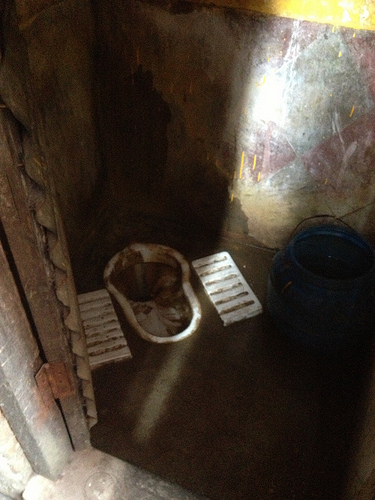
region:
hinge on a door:
[24, 357, 79, 411]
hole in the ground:
[97, 231, 216, 347]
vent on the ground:
[185, 250, 263, 335]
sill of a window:
[49, 439, 172, 498]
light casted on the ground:
[147, 343, 180, 456]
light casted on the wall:
[273, 29, 346, 200]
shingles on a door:
[57, 276, 113, 437]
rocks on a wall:
[1, 407, 56, 498]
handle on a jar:
[288, 213, 358, 234]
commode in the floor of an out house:
[103, 242, 200, 341]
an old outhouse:
[1, 2, 372, 497]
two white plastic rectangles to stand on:
[77, 251, 263, 367]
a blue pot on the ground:
[265, 215, 371, 355]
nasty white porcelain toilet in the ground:
[106, 236, 202, 341]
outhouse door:
[3, 47, 95, 445]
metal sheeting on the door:
[3, 14, 96, 429]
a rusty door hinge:
[35, 361, 73, 407]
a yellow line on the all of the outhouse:
[216, 0, 370, 26]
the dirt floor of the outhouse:
[86, 212, 358, 495]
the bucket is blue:
[264, 212, 371, 359]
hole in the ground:
[102, 239, 204, 346]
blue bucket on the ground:
[262, 210, 367, 355]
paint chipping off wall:
[9, 55, 373, 247]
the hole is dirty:
[104, 240, 195, 344]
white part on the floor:
[189, 251, 266, 328]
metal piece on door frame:
[27, 359, 76, 408]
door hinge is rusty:
[29, 358, 77, 408]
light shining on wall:
[204, 54, 371, 194]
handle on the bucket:
[284, 205, 362, 251]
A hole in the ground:
[97, 237, 208, 348]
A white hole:
[101, 236, 212, 357]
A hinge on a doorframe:
[32, 360, 77, 418]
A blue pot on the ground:
[256, 207, 364, 368]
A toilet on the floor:
[74, 235, 266, 371]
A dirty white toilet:
[98, 240, 216, 357]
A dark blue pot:
[263, 204, 368, 377]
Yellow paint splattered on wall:
[109, 1, 369, 221]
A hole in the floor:
[100, 226, 221, 359]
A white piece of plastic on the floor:
[191, 248, 268, 329]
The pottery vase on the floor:
[262, 207, 374, 362]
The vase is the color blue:
[261, 245, 373, 350]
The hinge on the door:
[34, 358, 78, 412]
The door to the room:
[2, 106, 111, 451]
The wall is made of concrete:
[91, 32, 284, 198]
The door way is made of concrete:
[1, 262, 89, 484]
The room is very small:
[47, 68, 370, 498]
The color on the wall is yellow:
[252, 0, 370, 24]